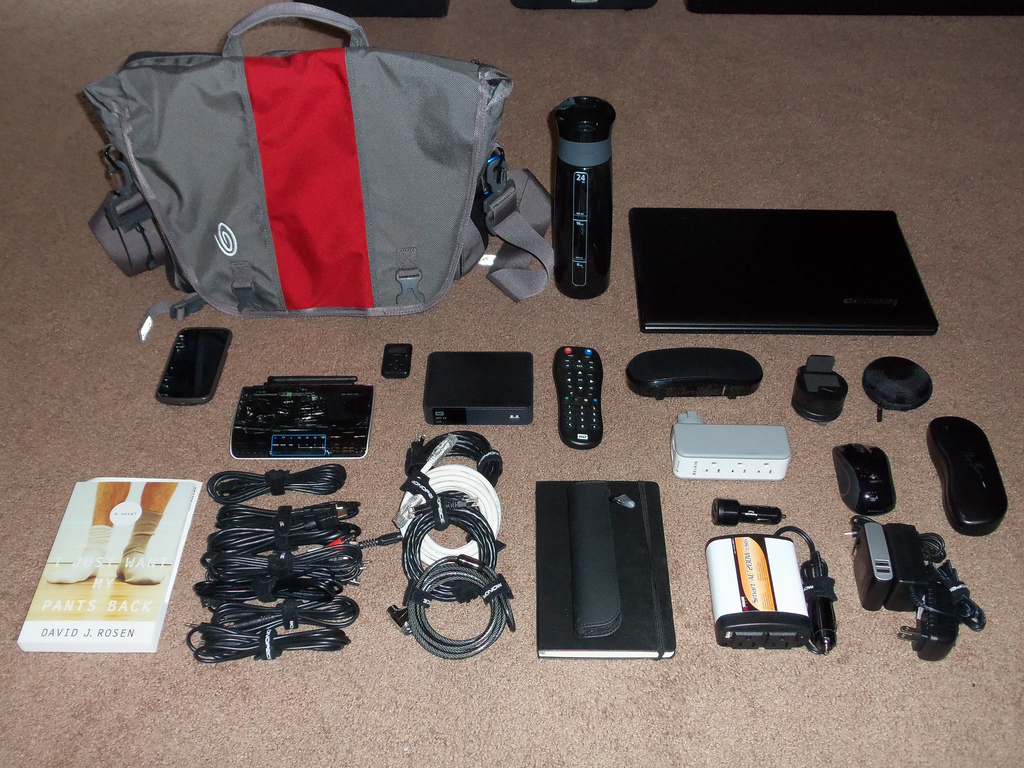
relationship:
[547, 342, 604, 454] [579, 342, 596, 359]
remote with button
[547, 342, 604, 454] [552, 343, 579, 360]
remote with button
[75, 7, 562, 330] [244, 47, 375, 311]
bag with stripe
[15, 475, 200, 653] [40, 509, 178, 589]
book with socks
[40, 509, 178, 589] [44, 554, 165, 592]
socks on feet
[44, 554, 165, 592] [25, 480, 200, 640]
feet on top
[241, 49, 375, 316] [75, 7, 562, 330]
stripe on bag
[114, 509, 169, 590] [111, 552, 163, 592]
sock on foot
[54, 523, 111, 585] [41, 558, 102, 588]
sock on foot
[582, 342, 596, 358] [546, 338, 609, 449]
button on remote